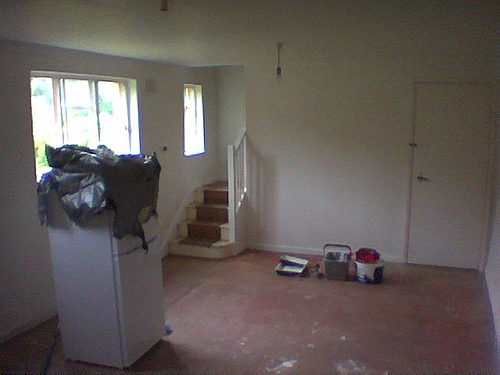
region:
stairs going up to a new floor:
[168, 172, 245, 253]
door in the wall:
[399, 69, 495, 231]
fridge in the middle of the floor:
[31, 172, 179, 366]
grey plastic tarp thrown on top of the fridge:
[37, 133, 159, 238]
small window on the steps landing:
[174, 77, 210, 160]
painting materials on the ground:
[266, 235, 386, 290]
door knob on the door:
[412, 168, 424, 184]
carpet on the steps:
[188, 180, 228, 249]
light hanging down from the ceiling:
[271, 39, 293, 88]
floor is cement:
[215, 308, 386, 360]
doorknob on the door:
[407, 168, 434, 188]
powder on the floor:
[262, 335, 374, 347]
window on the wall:
[162, 65, 207, 159]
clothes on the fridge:
[42, 145, 156, 229]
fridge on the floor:
[98, 313, 165, 368]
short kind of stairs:
[188, 173, 240, 248]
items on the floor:
[264, 237, 388, 293]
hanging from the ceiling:
[265, 32, 291, 86]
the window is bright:
[42, 85, 124, 133]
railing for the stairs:
[207, 127, 247, 232]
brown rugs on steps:
[195, 182, 220, 252]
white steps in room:
[181, 152, 246, 254]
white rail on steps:
[207, 136, 247, 268]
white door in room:
[428, 68, 495, 290]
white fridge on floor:
[51, 172, 188, 360]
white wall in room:
[261, 79, 406, 281]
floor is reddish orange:
[218, 270, 349, 371]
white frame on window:
[0, 92, 144, 153]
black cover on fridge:
[52, 135, 172, 230]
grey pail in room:
[318, 232, 343, 282]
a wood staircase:
[171, 128, 244, 263]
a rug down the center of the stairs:
[180, 180, 234, 267]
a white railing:
[225, 127, 250, 241]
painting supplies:
[269, 236, 403, 291]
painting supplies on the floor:
[269, 238, 399, 289]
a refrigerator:
[34, 140, 178, 368]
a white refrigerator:
[31, 139, 183, 369]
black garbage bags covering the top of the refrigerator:
[31, 139, 164, 251]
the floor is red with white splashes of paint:
[157, 244, 485, 374]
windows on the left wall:
[17, 66, 217, 196]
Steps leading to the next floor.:
[169, 148, 241, 273]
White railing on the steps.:
[215, 109, 251, 245]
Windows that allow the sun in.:
[4, 38, 150, 179]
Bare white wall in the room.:
[267, 74, 357, 234]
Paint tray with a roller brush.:
[267, 250, 311, 285]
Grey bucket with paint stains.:
[315, 229, 355, 282]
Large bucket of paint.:
[350, 230, 392, 287]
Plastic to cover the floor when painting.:
[25, 120, 177, 237]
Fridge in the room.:
[22, 120, 181, 367]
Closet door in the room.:
[388, 69, 491, 274]